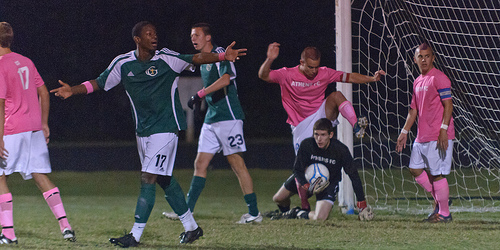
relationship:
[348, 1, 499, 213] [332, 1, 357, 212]
net to post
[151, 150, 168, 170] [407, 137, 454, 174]
17 on shorts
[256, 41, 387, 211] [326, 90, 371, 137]
man with leg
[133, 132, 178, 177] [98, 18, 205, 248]
shorts of player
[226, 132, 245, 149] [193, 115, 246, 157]
number 23 on pair of shorts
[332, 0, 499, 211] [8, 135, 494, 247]
goal on field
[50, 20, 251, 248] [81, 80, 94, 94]
man wearing armband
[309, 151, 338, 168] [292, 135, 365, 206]
letters on shirt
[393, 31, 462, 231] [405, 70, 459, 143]
man wearing shirt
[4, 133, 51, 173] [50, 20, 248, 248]
shorts of man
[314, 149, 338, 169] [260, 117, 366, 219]
shirt on man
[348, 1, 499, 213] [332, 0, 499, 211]
net in goal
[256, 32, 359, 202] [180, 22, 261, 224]
man wearing a black glove/man